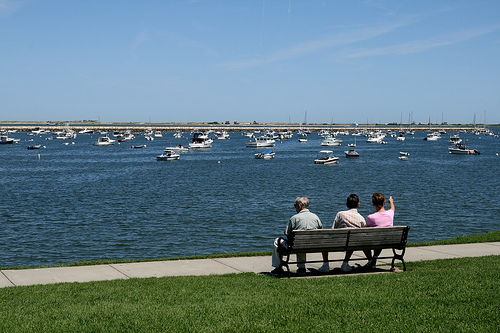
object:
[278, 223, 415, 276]
bench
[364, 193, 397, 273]
woman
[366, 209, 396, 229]
pink top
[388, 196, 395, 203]
hand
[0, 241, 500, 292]
sidewalk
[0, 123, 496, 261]
ocean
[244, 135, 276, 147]
boat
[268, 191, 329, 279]
man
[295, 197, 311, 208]
gray hair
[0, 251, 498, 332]
grass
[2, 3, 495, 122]
sky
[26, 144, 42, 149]
boat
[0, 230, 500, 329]
shore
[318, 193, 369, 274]
person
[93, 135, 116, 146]
boat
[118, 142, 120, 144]
motor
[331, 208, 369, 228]
plaid shirt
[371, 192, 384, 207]
short  hair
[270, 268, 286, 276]
shoes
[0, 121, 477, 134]
harbor